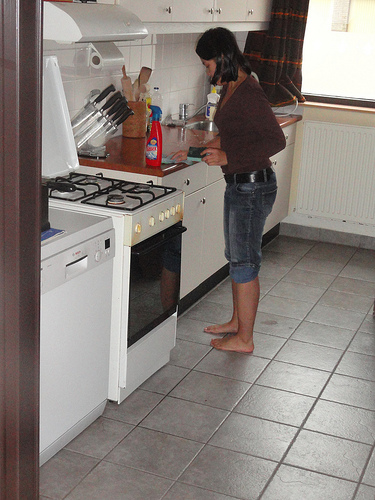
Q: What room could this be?
A: It is a kitchen.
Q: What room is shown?
A: It is a kitchen.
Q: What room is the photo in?
A: It is at the kitchen.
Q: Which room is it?
A: It is a kitchen.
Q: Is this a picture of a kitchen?
A: Yes, it is showing a kitchen.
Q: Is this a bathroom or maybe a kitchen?
A: It is a kitchen.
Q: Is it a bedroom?
A: No, it is a kitchen.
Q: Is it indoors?
A: Yes, it is indoors.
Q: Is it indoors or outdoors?
A: It is indoors.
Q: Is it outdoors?
A: No, it is indoors.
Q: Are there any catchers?
A: No, there are no catchers.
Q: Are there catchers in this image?
A: No, there are no catchers.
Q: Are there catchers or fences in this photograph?
A: No, there are no catchers or fences.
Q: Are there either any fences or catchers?
A: No, there are no catchers or fences.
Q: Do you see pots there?
A: No, there are no pots.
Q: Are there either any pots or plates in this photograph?
A: No, there are no pots or plates.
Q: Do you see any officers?
A: No, there are no officers.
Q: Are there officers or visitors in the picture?
A: No, there are no officers or visitors.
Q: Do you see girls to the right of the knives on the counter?
A: Yes, there is a girl to the right of the knives.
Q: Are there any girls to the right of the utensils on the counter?
A: Yes, there is a girl to the right of the knives.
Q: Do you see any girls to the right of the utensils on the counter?
A: Yes, there is a girl to the right of the knives.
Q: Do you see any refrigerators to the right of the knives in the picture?
A: No, there is a girl to the right of the knives.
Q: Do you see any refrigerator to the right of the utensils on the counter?
A: No, there is a girl to the right of the knives.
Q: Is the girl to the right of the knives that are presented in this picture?
A: Yes, the girl is to the right of the knives.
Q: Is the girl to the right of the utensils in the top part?
A: Yes, the girl is to the right of the knives.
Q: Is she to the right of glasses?
A: No, the girl is to the right of the knives.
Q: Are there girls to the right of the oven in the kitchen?
A: Yes, there is a girl to the right of the oven.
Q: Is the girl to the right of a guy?
A: No, the girl is to the right of the oven.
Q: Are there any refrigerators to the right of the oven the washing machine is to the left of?
A: No, there is a girl to the right of the oven.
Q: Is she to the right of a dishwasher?
A: No, the girl is to the right of the oven.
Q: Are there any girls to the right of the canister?
A: Yes, there is a girl to the right of the canister.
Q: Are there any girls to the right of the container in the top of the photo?
A: Yes, there is a girl to the right of the canister.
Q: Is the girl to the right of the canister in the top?
A: Yes, the girl is to the right of the canister.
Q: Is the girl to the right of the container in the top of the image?
A: Yes, the girl is to the right of the canister.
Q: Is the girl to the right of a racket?
A: No, the girl is to the right of the canister.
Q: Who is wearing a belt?
A: The girl is wearing a belt.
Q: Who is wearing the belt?
A: The girl is wearing a belt.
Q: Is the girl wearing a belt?
A: Yes, the girl is wearing a belt.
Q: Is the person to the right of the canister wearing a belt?
A: Yes, the girl is wearing a belt.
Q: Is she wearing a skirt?
A: No, the girl is wearing a belt.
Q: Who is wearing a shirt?
A: The girl is wearing a shirt.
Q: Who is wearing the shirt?
A: The girl is wearing a shirt.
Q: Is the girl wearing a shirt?
A: Yes, the girl is wearing a shirt.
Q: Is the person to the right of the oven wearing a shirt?
A: Yes, the girl is wearing a shirt.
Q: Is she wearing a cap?
A: No, the girl is wearing a shirt.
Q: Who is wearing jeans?
A: The girl is wearing jeans.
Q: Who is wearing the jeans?
A: The girl is wearing jeans.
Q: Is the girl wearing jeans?
A: Yes, the girl is wearing jeans.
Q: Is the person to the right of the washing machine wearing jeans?
A: Yes, the girl is wearing jeans.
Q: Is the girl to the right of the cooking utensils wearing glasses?
A: No, the girl is wearing jeans.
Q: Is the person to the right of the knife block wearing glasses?
A: No, the girl is wearing jeans.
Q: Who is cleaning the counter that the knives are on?
A: The girl is cleaning the counter.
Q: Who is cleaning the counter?
A: The girl is cleaning the counter.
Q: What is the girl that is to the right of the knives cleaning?
A: The girl is cleaning the counter.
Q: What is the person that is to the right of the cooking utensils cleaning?
A: The girl is cleaning the counter.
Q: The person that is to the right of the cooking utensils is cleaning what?
A: The girl is cleaning the counter.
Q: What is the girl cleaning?
A: The girl is cleaning the counter.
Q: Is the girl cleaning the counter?
A: Yes, the girl is cleaning the counter.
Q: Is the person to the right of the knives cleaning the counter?
A: Yes, the girl is cleaning the counter.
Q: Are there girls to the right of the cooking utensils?
A: Yes, there is a girl to the right of the cooking utensils.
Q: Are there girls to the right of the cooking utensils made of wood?
A: Yes, there is a girl to the right of the cooking utensils.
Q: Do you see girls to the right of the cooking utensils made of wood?
A: Yes, there is a girl to the right of the cooking utensils.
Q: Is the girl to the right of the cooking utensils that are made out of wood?
A: Yes, the girl is to the right of the cooking utensils.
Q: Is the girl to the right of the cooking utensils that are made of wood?
A: Yes, the girl is to the right of the cooking utensils.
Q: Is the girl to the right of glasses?
A: No, the girl is to the right of the cooking utensils.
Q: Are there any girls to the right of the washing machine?
A: Yes, there is a girl to the right of the washing machine.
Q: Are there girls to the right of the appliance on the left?
A: Yes, there is a girl to the right of the washing machine.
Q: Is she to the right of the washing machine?
A: Yes, the girl is to the right of the washing machine.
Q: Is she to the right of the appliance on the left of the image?
A: Yes, the girl is to the right of the washing machine.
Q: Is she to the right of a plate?
A: No, the girl is to the right of the washing machine.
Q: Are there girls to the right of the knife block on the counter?
A: Yes, there is a girl to the right of the knife block.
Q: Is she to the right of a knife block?
A: Yes, the girl is to the right of a knife block.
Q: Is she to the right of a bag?
A: No, the girl is to the right of a knife block.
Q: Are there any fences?
A: No, there are no fences.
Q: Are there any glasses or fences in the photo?
A: No, there are no fences or glasses.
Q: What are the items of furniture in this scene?
A: The pieces of furniture are cabinets.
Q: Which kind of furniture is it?
A: The pieces of furniture are cabinets.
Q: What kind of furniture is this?
A: These are cabinets.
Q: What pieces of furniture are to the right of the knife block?
A: The pieces of furniture are cabinets.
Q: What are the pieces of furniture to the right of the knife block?
A: The pieces of furniture are cabinets.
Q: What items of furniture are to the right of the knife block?
A: The pieces of furniture are cabinets.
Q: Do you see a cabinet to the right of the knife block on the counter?
A: Yes, there are cabinets to the right of the knife block.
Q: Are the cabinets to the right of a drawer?
A: No, the cabinets are to the right of the knife block.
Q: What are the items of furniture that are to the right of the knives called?
A: The pieces of furniture are cabinets.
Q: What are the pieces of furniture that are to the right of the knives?
A: The pieces of furniture are cabinets.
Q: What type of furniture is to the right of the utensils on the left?
A: The pieces of furniture are cabinets.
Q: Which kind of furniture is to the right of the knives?
A: The pieces of furniture are cabinets.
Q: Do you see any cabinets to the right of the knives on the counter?
A: Yes, there are cabinets to the right of the knives.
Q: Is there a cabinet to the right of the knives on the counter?
A: Yes, there are cabinets to the right of the knives.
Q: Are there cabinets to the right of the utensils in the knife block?
A: Yes, there are cabinets to the right of the knives.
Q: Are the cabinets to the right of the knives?
A: Yes, the cabinets are to the right of the knives.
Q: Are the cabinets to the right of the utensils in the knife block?
A: Yes, the cabinets are to the right of the knives.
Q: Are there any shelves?
A: No, there are no shelves.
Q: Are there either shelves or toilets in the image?
A: No, there are no shelves or toilets.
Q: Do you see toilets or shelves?
A: No, there are no shelves or toilets.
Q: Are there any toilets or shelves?
A: No, there are no shelves or toilets.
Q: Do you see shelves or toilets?
A: No, there are no shelves or toilets.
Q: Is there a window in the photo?
A: Yes, there is a window.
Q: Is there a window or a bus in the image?
A: Yes, there is a window.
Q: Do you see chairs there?
A: No, there are no chairs.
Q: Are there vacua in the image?
A: No, there are no vacua.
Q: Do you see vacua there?
A: No, there are no vacua.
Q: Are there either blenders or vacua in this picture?
A: No, there are no vacua or blenders.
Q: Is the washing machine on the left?
A: Yes, the washing machine is on the left of the image.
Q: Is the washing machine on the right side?
A: No, the washing machine is on the left of the image.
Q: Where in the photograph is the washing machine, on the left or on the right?
A: The washing machine is on the left of the image.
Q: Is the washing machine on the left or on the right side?
A: The washing machine is on the left of the image.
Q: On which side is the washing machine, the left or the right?
A: The washing machine is on the left of the image.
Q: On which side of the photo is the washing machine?
A: The washing machine is on the left of the image.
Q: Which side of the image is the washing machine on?
A: The washing machine is on the left of the image.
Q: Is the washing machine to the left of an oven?
A: Yes, the washing machine is to the left of an oven.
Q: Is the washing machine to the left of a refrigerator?
A: No, the washing machine is to the left of an oven.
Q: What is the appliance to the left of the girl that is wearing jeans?
A: The appliance is a washing machine.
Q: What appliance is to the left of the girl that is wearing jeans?
A: The appliance is a washing machine.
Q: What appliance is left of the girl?
A: The appliance is a washing machine.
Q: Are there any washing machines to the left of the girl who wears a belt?
A: Yes, there is a washing machine to the left of the girl.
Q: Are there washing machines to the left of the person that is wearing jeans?
A: Yes, there is a washing machine to the left of the girl.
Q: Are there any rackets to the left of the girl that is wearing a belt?
A: No, there is a washing machine to the left of the girl.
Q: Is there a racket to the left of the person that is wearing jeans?
A: No, there is a washing machine to the left of the girl.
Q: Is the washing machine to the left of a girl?
A: Yes, the washing machine is to the left of a girl.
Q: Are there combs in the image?
A: No, there are no combs.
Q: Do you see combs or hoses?
A: No, there are no combs or hoses.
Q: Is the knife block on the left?
A: Yes, the knife block is on the left of the image.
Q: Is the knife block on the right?
A: No, the knife block is on the left of the image.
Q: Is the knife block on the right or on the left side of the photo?
A: The knife block is on the left of the image.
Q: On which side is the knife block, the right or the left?
A: The knife block is on the left of the image.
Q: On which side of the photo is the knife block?
A: The knife block is on the left of the image.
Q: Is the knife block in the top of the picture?
A: Yes, the knife block is in the top of the image.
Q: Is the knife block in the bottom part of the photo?
A: No, the knife block is in the top of the image.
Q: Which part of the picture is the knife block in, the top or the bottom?
A: The knife block is in the top of the image.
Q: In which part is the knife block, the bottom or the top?
A: The knife block is in the top of the image.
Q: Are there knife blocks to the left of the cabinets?
A: Yes, there is a knife block to the left of the cabinets.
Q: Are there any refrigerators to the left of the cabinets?
A: No, there is a knife block to the left of the cabinets.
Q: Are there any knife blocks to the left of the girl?
A: Yes, there is a knife block to the left of the girl.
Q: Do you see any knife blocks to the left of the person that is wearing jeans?
A: Yes, there is a knife block to the left of the girl.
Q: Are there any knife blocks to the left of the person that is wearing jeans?
A: Yes, there is a knife block to the left of the girl.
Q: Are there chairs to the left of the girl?
A: No, there is a knife block to the left of the girl.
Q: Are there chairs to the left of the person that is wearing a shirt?
A: No, there is a knife block to the left of the girl.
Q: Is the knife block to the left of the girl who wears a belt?
A: Yes, the knife block is to the left of the girl.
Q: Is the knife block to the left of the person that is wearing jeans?
A: Yes, the knife block is to the left of the girl.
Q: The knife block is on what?
A: The knife block is on the counter.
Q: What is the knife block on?
A: The knife block is on the counter.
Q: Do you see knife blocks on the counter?
A: Yes, there is a knife block on the counter.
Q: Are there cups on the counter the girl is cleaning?
A: No, there is a knife block on the counter.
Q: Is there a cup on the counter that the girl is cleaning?
A: No, there is a knife block on the counter.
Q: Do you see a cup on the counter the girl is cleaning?
A: No, there is a knife block on the counter.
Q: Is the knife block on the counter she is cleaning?
A: Yes, the knife block is on the counter.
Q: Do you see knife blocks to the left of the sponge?
A: Yes, there is a knife block to the left of the sponge.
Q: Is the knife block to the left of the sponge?
A: Yes, the knife block is to the left of the sponge.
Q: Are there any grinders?
A: No, there are no grinders.